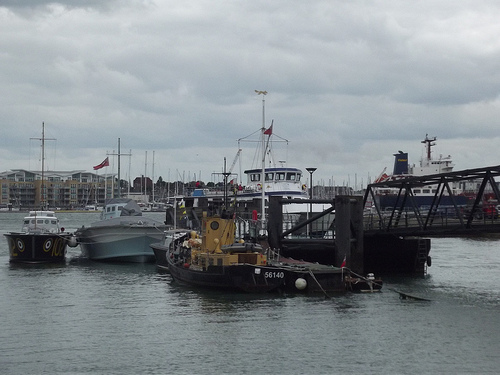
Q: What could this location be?
A: A marina.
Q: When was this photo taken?
A: Daylight.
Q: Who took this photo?
A: Photographer.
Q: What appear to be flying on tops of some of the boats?
A: Flags.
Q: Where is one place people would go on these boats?
A: Fishing.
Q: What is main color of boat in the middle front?
A: Yellow.